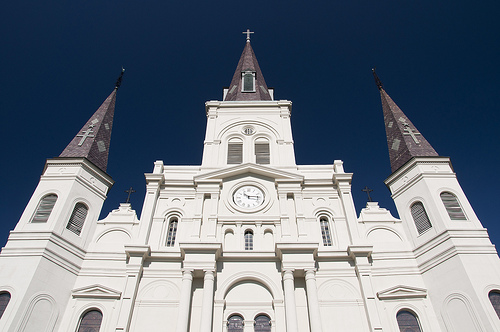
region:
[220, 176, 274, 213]
clock on face of building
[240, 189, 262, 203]
black hands of clock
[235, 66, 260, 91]
window on top of steeple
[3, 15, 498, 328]
one light stone church with three steeples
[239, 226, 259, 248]
small arched window on building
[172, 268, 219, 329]
two pillars on front of church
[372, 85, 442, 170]
thatched surface of steeple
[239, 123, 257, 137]
round barred vent on top of building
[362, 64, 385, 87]
pointed top of steeple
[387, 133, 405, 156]
grey diamond shape on side of steeple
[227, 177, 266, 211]
Clock on a building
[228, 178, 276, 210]
Clock is on a building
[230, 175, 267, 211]
Clock on front of a building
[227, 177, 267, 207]
Clock is on front of a building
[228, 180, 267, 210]
Clock on a church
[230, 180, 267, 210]
Clock is on a church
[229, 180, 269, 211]
Clock on front of a church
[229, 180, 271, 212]
Clock is on front of a church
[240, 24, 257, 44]
Cross on top of church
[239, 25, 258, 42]
Cross is on top of church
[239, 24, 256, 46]
cross is on the steple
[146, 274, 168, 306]
the building is white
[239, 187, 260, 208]
clock is on the building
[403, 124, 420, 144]
the cross is light gray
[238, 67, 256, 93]
window is on the steple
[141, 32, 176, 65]
sky is blue in color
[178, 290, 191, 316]
the pillar is white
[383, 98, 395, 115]
the steple is brownish red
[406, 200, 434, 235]
the window is boarded up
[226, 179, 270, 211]
a clock on the building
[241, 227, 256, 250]
an arched window case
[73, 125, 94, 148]
a cross on the tower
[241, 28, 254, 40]
a cross on the top of the church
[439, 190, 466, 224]
the window is closed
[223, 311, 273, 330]
a double arch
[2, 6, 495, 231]
no clouds in the sky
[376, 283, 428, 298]
a triangular accent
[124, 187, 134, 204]
a metal cross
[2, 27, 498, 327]
a large white church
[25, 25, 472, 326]
the church is white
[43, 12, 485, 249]
looking up at a church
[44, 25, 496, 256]
the spires are brown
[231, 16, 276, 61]
crucifix at top of tower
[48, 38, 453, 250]
there are three spires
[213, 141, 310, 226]
the clock face is white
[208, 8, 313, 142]
there is a window in the spire